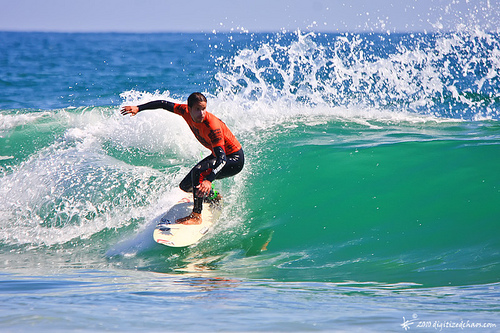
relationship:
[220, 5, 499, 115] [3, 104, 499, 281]
foam from wave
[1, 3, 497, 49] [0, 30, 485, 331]
sky meets ocean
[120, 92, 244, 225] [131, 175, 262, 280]
man on surfboard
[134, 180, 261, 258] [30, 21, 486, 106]
surfboard in ocean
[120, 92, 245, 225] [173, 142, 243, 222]
surfer wearing pants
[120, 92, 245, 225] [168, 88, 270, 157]
surfer wearing shirt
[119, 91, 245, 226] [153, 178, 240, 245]
man on surfboard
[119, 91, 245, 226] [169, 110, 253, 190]
man wears wetsuit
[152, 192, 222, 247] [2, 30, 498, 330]
surfboard on water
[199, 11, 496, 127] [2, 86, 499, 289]
ocean spray on waves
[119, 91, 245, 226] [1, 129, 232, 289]
man rides wave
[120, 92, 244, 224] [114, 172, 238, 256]
person rides surfboard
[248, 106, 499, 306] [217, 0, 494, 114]
ocean has spray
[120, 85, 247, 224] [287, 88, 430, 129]
person rides wave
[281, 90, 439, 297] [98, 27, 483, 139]
wave in ocean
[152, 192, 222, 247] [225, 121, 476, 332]
surfboard in water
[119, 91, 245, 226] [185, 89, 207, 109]
man has brown hair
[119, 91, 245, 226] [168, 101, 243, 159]
man wears shirt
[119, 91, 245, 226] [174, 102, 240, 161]
man wears shirt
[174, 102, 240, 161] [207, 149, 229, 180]
shirt has sleeve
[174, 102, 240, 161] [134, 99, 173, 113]
shirt has sleeve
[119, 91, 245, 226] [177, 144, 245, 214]
man wearing pants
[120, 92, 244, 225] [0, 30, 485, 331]
man surfing in ocean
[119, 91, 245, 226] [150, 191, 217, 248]
man surfing on surfboard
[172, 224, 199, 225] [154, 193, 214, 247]
left foot on surfboard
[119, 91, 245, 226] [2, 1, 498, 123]
man surging in sea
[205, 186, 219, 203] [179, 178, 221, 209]
strap around leg